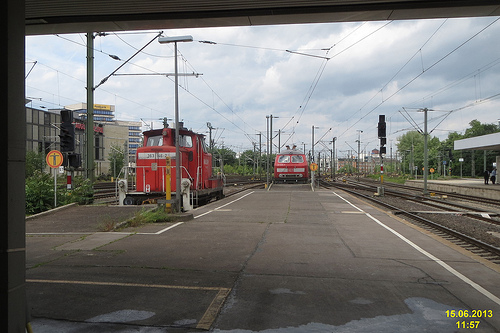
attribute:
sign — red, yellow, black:
[45, 150, 63, 205]